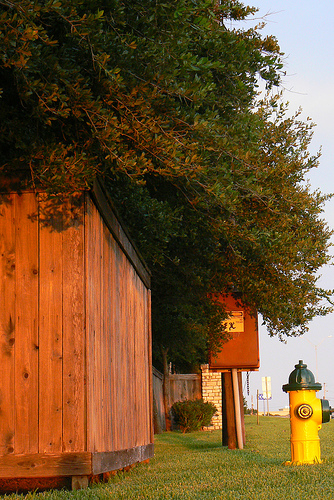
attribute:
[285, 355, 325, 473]
hydrant — green, yellow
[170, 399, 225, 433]
bush — short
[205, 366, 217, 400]
pillar — brick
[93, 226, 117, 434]
fence — tall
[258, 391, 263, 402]
sign — blue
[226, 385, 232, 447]
post — wooden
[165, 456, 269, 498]
grass — green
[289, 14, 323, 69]
sky — blue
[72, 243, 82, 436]
panel — vertical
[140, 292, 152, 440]
panel — vertical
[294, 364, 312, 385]
top — green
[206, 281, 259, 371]
metal sign — brown 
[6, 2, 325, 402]
tree — green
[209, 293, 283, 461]
sign — back, street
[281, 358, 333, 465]
fire hydrant — yellow, green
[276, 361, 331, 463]
hydrant — green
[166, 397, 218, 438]
bush — green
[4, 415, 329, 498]
grass — green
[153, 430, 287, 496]
grass — green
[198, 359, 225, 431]
column — stone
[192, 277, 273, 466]
box — red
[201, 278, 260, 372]
box — rusted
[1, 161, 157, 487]
building — brown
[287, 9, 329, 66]
sky — blue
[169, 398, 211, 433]
bush — Green 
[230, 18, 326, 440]
sky — blue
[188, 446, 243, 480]
grass — green